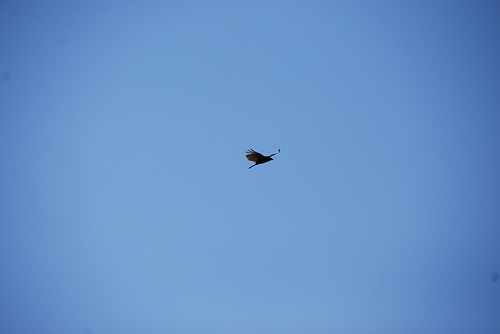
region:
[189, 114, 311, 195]
an airplane in the sky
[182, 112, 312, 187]
an airplane high in the sky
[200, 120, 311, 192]
an airplane flying in the sky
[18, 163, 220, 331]
a clear blue sky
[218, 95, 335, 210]
an airplane flying in the sky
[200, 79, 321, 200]
a plane alone in the sky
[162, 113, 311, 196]
a plane flying along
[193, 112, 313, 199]
a plane flying during the day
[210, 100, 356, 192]
a plane flying on a clear day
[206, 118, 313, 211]
a flying bird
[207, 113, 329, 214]
the bird is in the air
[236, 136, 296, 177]
the bird has a wing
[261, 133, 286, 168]
the bird has a tail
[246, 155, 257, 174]
the bird has a head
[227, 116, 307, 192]
the bird is black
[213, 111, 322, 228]
the bird looks small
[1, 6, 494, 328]
the sky is clear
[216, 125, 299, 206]
the bird is dark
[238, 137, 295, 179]
the bird's wing is out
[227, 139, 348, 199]
bird flying through the sky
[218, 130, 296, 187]
bird with large wing span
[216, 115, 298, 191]
bird with three wing feathers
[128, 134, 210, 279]
cloudless light blue sky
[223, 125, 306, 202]
bird with a long white neck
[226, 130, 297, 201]
black bird in the sky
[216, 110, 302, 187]
bird flying south all alone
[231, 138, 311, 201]
bird with several feathers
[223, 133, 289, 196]
bird with long tail feathers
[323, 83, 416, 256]
empty blue sky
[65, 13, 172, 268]
the sky is blue and clear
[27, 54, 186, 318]
the sky is blue and clear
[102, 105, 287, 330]
the sky is blue and clear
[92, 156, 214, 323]
the sky is blue and clear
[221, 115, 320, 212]
lonely bird in the sky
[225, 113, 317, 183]
bird flying alone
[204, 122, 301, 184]
bird with long white neck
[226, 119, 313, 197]
bird with long feathers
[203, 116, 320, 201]
bird with long black tail feathers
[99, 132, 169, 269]
clear and cloudless blue sky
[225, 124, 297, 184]
bird soaring through the air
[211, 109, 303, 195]
bird flying south for the winter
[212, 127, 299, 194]
bird with a wide wingspan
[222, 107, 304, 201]
flying through the cloudless sky